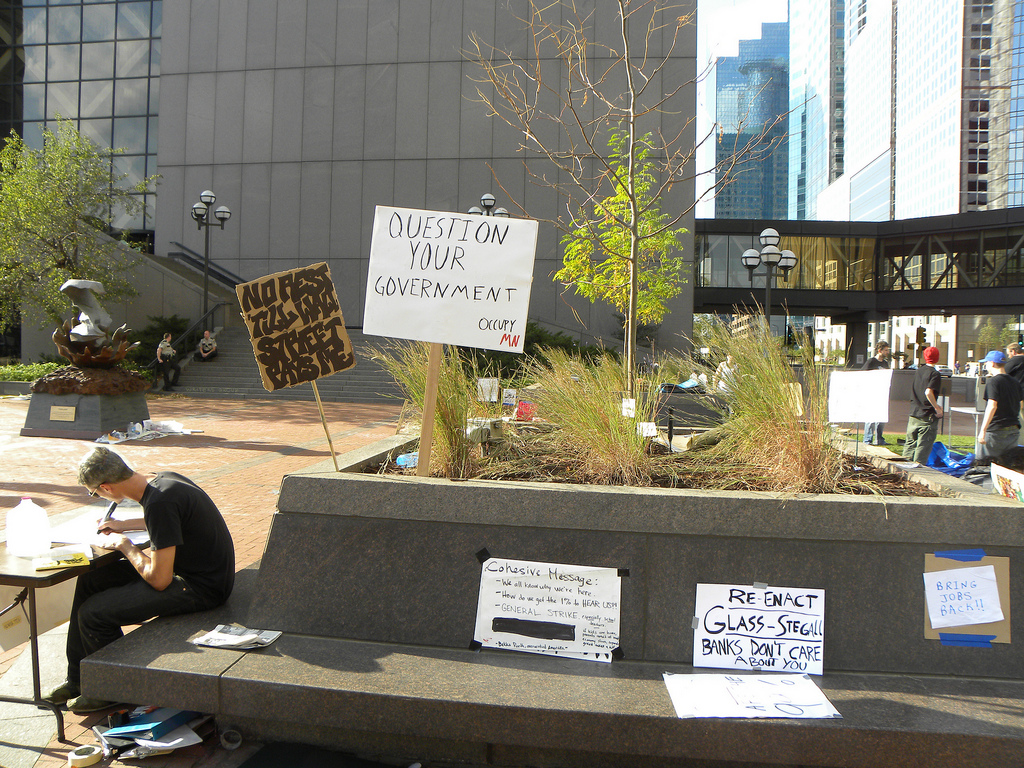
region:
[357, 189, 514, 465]
White sign attached to post.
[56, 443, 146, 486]
Person has gray hair.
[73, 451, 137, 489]
Person has short hair.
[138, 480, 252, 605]
Person wearing black shirt.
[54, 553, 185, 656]
Person wearing dark pants.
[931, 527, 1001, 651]
Blue tape attaching sign to wall.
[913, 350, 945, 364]
Person wearing red hat on head.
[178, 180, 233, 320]
Light pole with three lights on them.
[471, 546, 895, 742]
Three signs on the side of the bench.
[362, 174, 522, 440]
Small sign on top of the stick.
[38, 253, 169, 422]
Silver statue in the middle of the pavement.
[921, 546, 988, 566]
Blue tape on top of the whtie paper.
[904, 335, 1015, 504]
Two people standing on the concrete.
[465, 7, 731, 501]
Thin tree with branches and no leaves.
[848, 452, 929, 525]
Brown mulch around the trees.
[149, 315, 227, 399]
Two people standing on top of the stairs.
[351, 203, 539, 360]
white posterboard with black writing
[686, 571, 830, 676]
taped white sign with black writing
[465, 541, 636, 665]
black tape holding a white sign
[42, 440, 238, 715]
man leaning over writing with permanent marker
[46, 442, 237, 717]
man wearing black shirt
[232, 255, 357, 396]
black writing on cardboard sign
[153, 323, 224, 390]
two police officers conversing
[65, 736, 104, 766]
roll of duct tape on the ground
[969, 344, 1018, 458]
man wearing blue cap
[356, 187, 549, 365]
handmade sign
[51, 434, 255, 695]
man is sitting on a bench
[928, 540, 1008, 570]
blue tape holding up the sign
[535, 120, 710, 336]
bright green leaves on the small tree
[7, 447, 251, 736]
man is leaning over a table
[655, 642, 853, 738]
sign is laying on a bench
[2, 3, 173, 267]
wall is covered in windows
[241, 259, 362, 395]
brown and black sign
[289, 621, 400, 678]
shadow on the bench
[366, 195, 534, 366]
white sign hanging in dirt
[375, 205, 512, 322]
black writing on sign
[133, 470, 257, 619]
black shirt on person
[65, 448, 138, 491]
gray hair on person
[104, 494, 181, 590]
the person's left arm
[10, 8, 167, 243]
windows on the building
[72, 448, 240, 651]
man in black sitting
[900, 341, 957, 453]
person standing up outside